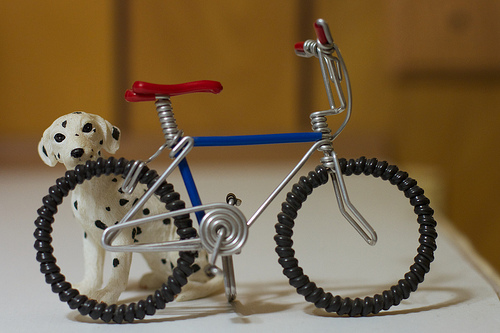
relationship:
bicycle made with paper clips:
[27, 18, 438, 326] [33, 16, 437, 331]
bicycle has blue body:
[27, 18, 438, 326] [171, 127, 319, 232]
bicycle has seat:
[27, 18, 438, 326] [122, 76, 227, 108]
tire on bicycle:
[274, 152, 439, 317] [27, 18, 438, 326]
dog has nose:
[36, 106, 236, 307] [63, 141, 93, 168]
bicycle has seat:
[27, 18, 443, 325] [121, 70, 228, 107]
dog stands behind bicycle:
[36, 106, 236, 307] [27, 18, 443, 325]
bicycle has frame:
[27, 18, 438, 326] [96, 110, 385, 253]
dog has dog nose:
[36, 106, 236, 307] [70, 148, 85, 158]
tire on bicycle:
[274, 152, 439, 317] [27, 18, 443, 325]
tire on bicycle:
[32, 154, 203, 324] [27, 18, 443, 325]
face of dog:
[25, 105, 130, 167] [43, 110, 210, 301]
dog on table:
[36, 109, 223, 324] [1, 145, 483, 331]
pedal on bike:
[192, 257, 232, 282] [35, 39, 456, 312]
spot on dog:
[109, 126, 122, 141] [35, 110, 225, 321]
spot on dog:
[92, 218, 109, 231] [35, 110, 225, 321]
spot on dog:
[117, 195, 130, 206] [35, 110, 225, 321]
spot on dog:
[140, 206, 150, 215] [35, 110, 225, 321]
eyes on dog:
[51, 120, 95, 144] [28, 15, 441, 325]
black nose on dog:
[51, 148, 103, 169] [36, 106, 236, 307]